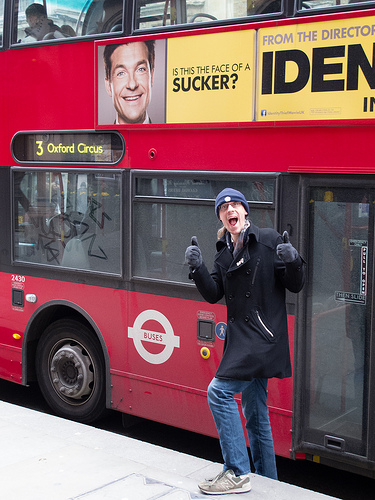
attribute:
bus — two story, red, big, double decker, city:
[2, 2, 373, 488]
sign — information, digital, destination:
[14, 132, 123, 166]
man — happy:
[185, 188, 304, 495]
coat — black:
[199, 229, 293, 375]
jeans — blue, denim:
[205, 375, 279, 479]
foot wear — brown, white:
[196, 461, 249, 497]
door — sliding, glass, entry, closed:
[296, 179, 368, 458]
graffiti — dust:
[16, 196, 112, 266]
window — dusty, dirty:
[13, 167, 122, 278]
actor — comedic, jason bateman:
[101, 41, 153, 123]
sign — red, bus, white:
[125, 312, 186, 366]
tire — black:
[35, 318, 105, 416]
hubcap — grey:
[50, 342, 89, 394]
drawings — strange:
[28, 199, 118, 267]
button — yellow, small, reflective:
[198, 344, 210, 357]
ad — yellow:
[170, 27, 372, 106]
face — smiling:
[220, 201, 245, 231]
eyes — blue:
[213, 201, 242, 213]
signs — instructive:
[331, 235, 370, 324]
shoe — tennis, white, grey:
[196, 456, 254, 499]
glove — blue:
[187, 236, 205, 272]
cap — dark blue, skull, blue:
[214, 188, 242, 208]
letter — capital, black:
[274, 48, 310, 95]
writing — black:
[18, 174, 112, 270]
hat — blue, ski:
[210, 185, 246, 217]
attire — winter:
[191, 231, 298, 481]